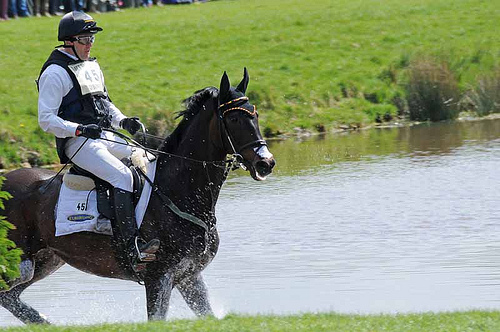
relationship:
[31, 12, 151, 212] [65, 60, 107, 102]
man has a chest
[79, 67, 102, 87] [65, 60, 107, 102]
45 on h chest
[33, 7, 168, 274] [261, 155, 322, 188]
man wearing a black hat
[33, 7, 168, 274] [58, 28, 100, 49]
man wearing googles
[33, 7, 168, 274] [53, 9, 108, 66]
man wearing hat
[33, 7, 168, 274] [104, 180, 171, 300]
man wearing boots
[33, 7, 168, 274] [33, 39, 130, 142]
man has vest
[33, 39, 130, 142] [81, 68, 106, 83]
vest with 45